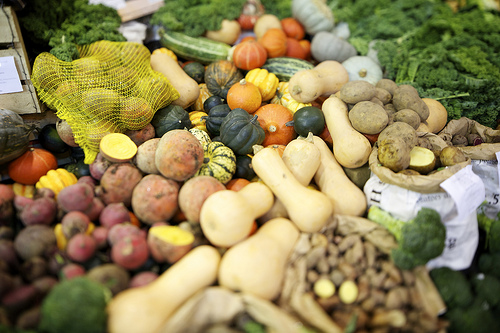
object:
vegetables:
[37, 44, 375, 317]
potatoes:
[15, 226, 54, 264]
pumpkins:
[219, 107, 267, 153]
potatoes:
[33, 30, 180, 140]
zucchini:
[162, 33, 228, 65]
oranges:
[226, 77, 264, 114]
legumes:
[307, 227, 419, 324]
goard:
[225, 41, 273, 67]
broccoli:
[367, 205, 447, 273]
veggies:
[50, 174, 153, 274]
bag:
[28, 30, 182, 164]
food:
[97, 133, 137, 162]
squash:
[249, 150, 339, 236]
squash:
[200, 180, 271, 246]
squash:
[217, 215, 298, 298]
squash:
[106, 242, 222, 328]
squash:
[258, 128, 321, 217]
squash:
[320, 93, 373, 169]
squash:
[290, 59, 350, 104]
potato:
[374, 122, 424, 168]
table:
[5, 16, 497, 325]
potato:
[353, 99, 392, 132]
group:
[195, 133, 424, 326]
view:
[65, 10, 443, 294]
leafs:
[39, 273, 105, 324]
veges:
[375, 16, 499, 117]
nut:
[42, 44, 189, 131]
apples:
[31, 40, 180, 165]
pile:
[148, 47, 343, 178]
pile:
[112, 141, 205, 217]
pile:
[44, 156, 198, 267]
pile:
[67, 255, 212, 327]